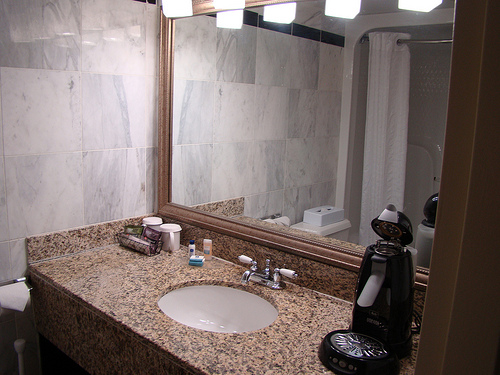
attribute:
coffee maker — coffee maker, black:
[317, 202, 418, 374]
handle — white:
[271, 268, 300, 287]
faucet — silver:
[235, 253, 299, 293]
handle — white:
[235, 254, 260, 275]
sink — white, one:
[152, 278, 280, 336]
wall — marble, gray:
[2, 0, 155, 218]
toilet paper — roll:
[1, 283, 32, 312]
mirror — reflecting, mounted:
[173, 0, 457, 271]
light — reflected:
[212, 9, 244, 31]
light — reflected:
[261, 5, 296, 27]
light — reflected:
[325, 0, 363, 20]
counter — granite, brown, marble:
[24, 217, 422, 374]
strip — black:
[243, 11, 349, 46]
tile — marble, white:
[85, 74, 145, 151]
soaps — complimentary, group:
[127, 227, 161, 244]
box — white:
[304, 205, 345, 224]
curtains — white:
[356, 33, 410, 247]